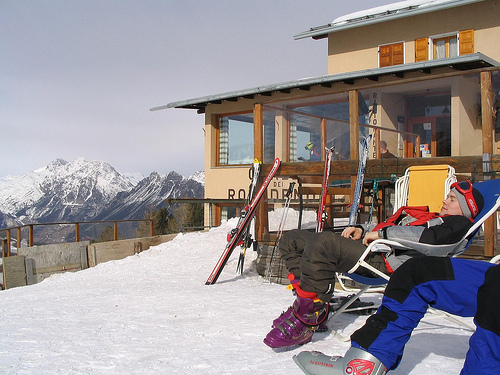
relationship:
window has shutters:
[426, 28, 462, 65] [456, 28, 477, 60]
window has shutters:
[426, 28, 462, 65] [413, 33, 429, 70]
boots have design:
[285, 330, 399, 375] [335, 353, 379, 374]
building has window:
[149, 0, 494, 220] [426, 28, 462, 65]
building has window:
[149, 0, 494, 220] [374, 35, 407, 78]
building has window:
[149, 0, 494, 220] [208, 100, 282, 178]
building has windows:
[149, 0, 494, 220] [285, 97, 373, 162]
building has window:
[149, 0, 494, 220] [387, 79, 470, 122]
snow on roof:
[328, 0, 447, 25] [280, 1, 500, 45]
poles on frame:
[263, 182, 296, 283] [249, 152, 499, 293]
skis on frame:
[195, 157, 285, 291] [249, 152, 499, 293]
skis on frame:
[303, 140, 345, 250] [249, 152, 499, 293]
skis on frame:
[341, 127, 379, 248] [249, 152, 499, 293]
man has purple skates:
[261, 178, 486, 350] [262, 292, 344, 354]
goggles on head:
[447, 177, 484, 221] [435, 176, 486, 228]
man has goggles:
[261, 178, 486, 350] [447, 177, 484, 221]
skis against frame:
[195, 157, 285, 291] [249, 152, 499, 293]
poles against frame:
[263, 182, 296, 283] [249, 152, 499, 293]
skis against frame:
[303, 140, 345, 250] [249, 152, 499, 293]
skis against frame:
[341, 127, 379, 248] [249, 152, 499, 293]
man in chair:
[261, 178, 486, 350] [325, 173, 499, 363]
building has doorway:
[149, 0, 494, 220] [402, 113, 456, 167]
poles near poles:
[263, 182, 296, 283] [263, 182, 296, 283]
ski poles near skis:
[361, 177, 385, 237] [341, 127, 379, 248]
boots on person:
[285, 330, 399, 375] [278, 227, 500, 374]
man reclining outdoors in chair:
[261, 178, 486, 350] [324, 175, 499, 328]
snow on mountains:
[15, 177, 34, 188] [2, 156, 204, 227]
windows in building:
[217, 90, 357, 168] [149, 0, 494, 220]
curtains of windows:
[211, 132, 244, 156] [217, 90, 357, 168]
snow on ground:
[115, 252, 215, 337] [2, 219, 494, 369]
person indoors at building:
[294, 130, 321, 164] [149, 0, 499, 259]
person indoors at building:
[374, 139, 394, 158] [149, 0, 499, 259]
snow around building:
[0, 202, 500, 375] [149, 0, 499, 259]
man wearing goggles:
[271, 189, 498, 261] [449, 179, 479, 218]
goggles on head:
[449, 179, 479, 218] [437, 179, 485, 220]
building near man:
[149, 0, 494, 220] [278, 175, 485, 335]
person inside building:
[374, 139, 398, 159] [150, 0, 498, 260]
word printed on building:
[225, 186, 315, 203] [149, 0, 494, 220]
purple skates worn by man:
[262, 292, 344, 354] [260, 179, 482, 351]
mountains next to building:
[0, 156, 207, 258] [149, 0, 499, 259]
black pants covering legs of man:
[281, 231, 393, 297] [261, 178, 486, 350]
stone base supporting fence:
[8, 232, 179, 295] [3, 220, 154, 254]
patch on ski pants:
[383, 252, 458, 304] [346, 245, 499, 372]